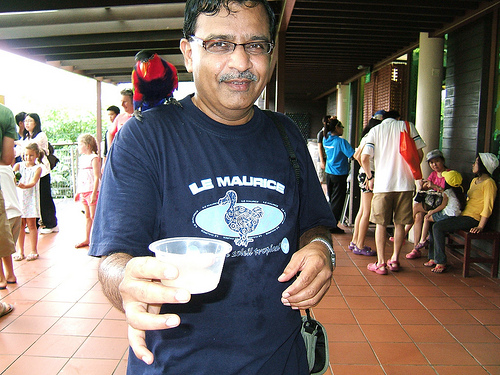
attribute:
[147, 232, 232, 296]
cup — clear, plastic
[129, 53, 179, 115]
bird — red, black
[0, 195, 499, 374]
red pavement — smooth paved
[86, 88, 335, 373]
blue shirt — graphic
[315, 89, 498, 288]
people — standing, sitting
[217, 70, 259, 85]
moustache — grey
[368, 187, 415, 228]
shorts — brown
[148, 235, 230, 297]
container — plastic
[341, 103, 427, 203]
shirt — white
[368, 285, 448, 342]
floor — brown, tiled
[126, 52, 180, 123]
bird — red, black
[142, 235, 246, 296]
cup — clear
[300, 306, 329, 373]
bag — small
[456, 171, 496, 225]
shirt — yellow